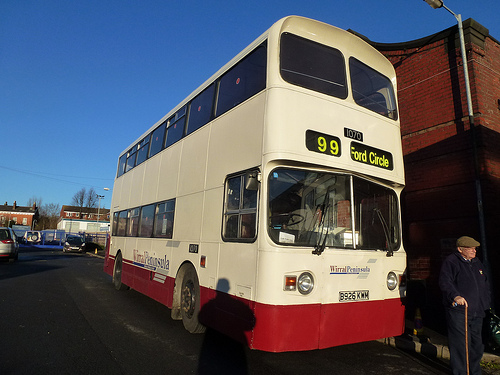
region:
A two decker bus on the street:
[83, 52, 445, 355]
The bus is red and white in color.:
[96, 80, 434, 349]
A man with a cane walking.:
[432, 209, 490, 371]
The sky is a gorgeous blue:
[18, 24, 105, 222]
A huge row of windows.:
[115, 36, 402, 113]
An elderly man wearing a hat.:
[440, 216, 486, 269]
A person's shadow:
[161, 226, 299, 373]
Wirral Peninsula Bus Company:
[102, 222, 234, 314]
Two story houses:
[3, 185, 115, 265]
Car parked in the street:
[11, 208, 95, 258]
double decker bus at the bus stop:
[102, 13, 404, 353]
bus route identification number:
[305, 126, 342, 157]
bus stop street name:
[350, 140, 390, 166]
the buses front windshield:
[265, 165, 400, 250]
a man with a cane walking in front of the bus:
[440, 235, 490, 370]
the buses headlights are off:
[296, 270, 311, 290]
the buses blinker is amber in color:
[284, 274, 298, 288]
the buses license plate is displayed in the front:
[337, 290, 367, 300]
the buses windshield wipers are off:
[310, 182, 330, 252]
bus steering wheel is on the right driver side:
[268, 210, 303, 225]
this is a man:
[445, 236, 486, 364]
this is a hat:
[456, 234, 481, 250]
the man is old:
[439, 232, 491, 368]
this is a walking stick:
[457, 300, 472, 374]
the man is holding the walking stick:
[451, 289, 469, 314]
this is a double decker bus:
[103, 14, 405, 334]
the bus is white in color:
[172, 153, 214, 178]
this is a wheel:
[175, 268, 203, 335]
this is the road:
[36, 261, 78, 340]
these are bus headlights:
[289, 266, 404, 299]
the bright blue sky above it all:
[1, 2, 498, 213]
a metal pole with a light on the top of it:
[418, 0, 499, 316]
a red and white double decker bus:
[103, 13, 414, 347]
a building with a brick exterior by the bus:
[385, 28, 498, 304]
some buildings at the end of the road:
[5, 205, 107, 247]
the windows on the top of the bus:
[106, 32, 403, 178]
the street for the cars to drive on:
[1, 247, 424, 372]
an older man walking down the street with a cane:
[432, 231, 497, 373]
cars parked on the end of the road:
[16, 227, 75, 249]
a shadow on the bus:
[192, 278, 259, 372]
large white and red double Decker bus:
[71, 10, 421, 343]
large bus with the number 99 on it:
[297, 120, 349, 171]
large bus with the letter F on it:
[346, 144, 359, 164]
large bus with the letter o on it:
[353, 153, 362, 165]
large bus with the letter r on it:
[355, 150, 367, 166]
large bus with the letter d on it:
[357, 148, 371, 166]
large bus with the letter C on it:
[366, 149, 382, 169]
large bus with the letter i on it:
[370, 149, 380, 169]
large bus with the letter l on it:
[375, 151, 391, 177]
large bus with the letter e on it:
[372, 156, 400, 176]